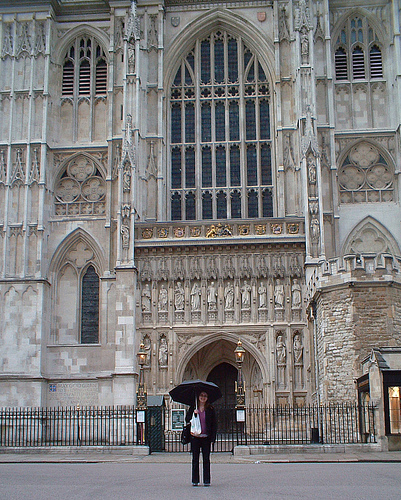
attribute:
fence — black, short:
[1, 407, 379, 444]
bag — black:
[181, 418, 191, 446]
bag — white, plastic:
[189, 410, 202, 435]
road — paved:
[6, 466, 228, 498]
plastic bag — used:
[191, 409, 202, 434]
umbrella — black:
[168, 378, 220, 403]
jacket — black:
[185, 402, 218, 442]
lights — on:
[112, 325, 302, 377]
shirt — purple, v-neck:
[197, 406, 207, 434]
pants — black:
[191, 438, 211, 479]